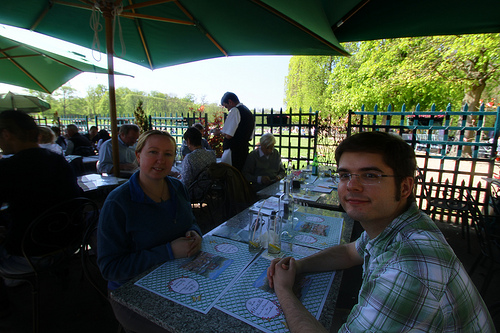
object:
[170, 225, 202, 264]
hands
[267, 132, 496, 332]
guy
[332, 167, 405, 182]
glasses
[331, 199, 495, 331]
shirt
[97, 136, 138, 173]
shirt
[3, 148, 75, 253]
shirt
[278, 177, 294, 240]
clear bottle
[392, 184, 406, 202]
cheek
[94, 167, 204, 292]
jacket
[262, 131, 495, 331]
man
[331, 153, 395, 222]
face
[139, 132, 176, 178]
face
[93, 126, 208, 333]
woman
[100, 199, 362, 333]
table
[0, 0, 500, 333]
ground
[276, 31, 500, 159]
tree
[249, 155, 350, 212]
table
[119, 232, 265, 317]
mat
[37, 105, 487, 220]
fence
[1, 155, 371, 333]
dining area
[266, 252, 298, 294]
hands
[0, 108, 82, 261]
man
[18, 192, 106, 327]
chair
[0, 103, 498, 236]
fence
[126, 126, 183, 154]
hair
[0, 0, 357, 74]
canopy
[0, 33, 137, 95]
canopy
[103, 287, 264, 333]
edge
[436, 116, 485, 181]
part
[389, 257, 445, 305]
part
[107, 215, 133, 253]
part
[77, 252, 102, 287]
part